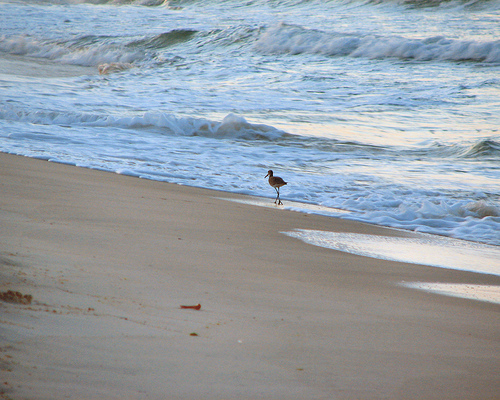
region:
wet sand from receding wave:
[281, 198, 497, 312]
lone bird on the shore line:
[248, 163, 295, 213]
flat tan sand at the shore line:
[0, 177, 465, 385]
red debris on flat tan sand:
[177, 293, 207, 320]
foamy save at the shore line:
[341, 170, 486, 242]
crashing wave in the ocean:
[120, 20, 479, 82]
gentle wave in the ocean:
[109, 98, 286, 156]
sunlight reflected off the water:
[312, 93, 489, 278]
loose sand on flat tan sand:
[3, 253, 71, 321]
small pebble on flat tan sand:
[176, 321, 206, 346]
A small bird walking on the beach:
[264, 167, 295, 208]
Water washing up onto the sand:
[277, 207, 497, 303]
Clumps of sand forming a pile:
[0, 272, 52, 316]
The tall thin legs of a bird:
[270, 186, 288, 203]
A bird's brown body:
[264, 170, 286, 188]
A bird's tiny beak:
[262, 173, 271, 180]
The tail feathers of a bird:
[274, 177, 290, 185]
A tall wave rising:
[128, 24, 497, 71]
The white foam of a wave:
[363, 180, 488, 244]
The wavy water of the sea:
[19, 0, 499, 232]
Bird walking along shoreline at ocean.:
[263, 169, 287, 205]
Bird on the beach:
[235, 149, 322, 237]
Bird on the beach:
[251, 159, 301, 227]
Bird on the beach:
[258, 160, 294, 203]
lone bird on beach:
[262, 168, 289, 205]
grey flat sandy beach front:
[3, 150, 479, 391]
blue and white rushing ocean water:
[5, 0, 499, 250]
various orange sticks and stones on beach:
[5, 255, 212, 327]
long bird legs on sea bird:
[271, 182, 287, 207]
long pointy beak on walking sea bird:
[261, 170, 271, 179]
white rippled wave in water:
[25, 93, 497, 154]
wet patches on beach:
[228, 194, 496, 314]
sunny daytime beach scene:
[2, 5, 495, 392]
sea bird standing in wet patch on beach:
[213, 150, 358, 219]